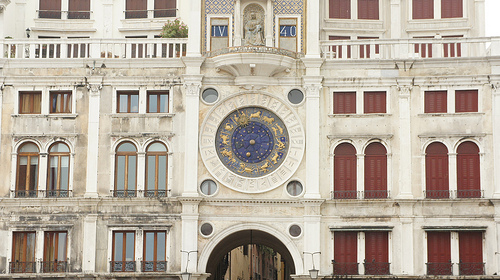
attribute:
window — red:
[421, 91, 442, 113]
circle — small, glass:
[196, 84, 227, 115]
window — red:
[329, 139, 356, 201]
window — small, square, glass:
[116, 91, 138, 112]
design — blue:
[234, 121, 272, 161]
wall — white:
[394, 91, 422, 219]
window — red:
[363, 89, 395, 119]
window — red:
[423, 87, 478, 115]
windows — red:
[333, 142, 387, 199]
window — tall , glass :
[111, 224, 135, 279]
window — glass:
[41, 227, 70, 274]